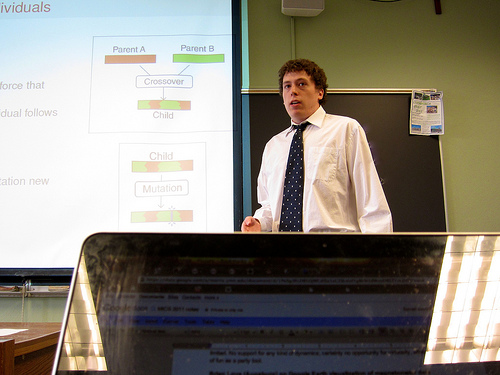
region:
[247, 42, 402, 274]
This is a person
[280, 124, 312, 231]
a black tie with wshite dots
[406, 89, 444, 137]
a news page attached to the wall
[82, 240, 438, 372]
the laptop displayed information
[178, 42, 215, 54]
the phrase parent B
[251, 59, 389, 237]
a man explaining about genetics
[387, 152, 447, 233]
an empty blackboard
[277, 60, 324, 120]
the head of the man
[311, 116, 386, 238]
the long sleeve white shirt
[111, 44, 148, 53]
the phrase Parent A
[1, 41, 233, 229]
the projection of the laptop display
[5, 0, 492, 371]
A man is giving a presentation.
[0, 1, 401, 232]
A man is standing next to a projecter screen.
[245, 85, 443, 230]
A blackboard is behind the man.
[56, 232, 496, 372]
A laptop is in the foreground.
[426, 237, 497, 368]
A light is reflected off the laptop screen.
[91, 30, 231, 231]
A graph is on the projector screen.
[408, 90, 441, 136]
A paper is hanging on the board.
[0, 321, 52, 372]
A wood table is partially visible.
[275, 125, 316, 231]
The man is wearing a tie.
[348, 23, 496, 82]
The wall is green.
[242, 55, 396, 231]
nervous guy presenting wearing blue tie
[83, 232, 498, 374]
Reflection on the computer screen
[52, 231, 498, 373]
Computer screen turned off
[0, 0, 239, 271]
Presentation projected on White background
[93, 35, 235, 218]
Flow chart on presentation.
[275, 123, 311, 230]
Blue and white polka dot tie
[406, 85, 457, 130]
Poster attached to the chalkboard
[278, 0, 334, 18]
White speaker box mounted to walk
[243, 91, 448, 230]
Black chalkboard behind kid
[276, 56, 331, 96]
Jewish Afro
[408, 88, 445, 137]
Paper with pictures on it and writing on the black board.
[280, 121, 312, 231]
Blue tie with white spots on it.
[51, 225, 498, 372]
Laptop that is switched on with the reflection of lights on it.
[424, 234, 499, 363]
Reflection of white lights on the laptop screen.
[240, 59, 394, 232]
A man in a long sleeve white shirt with curly brown hair.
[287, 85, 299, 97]
Nose on the face of a man.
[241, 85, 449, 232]
A black board behind a man.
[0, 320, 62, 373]
A brown wood desk.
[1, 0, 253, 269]
A white projector screen with a spreadsheet on it.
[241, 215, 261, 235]
Right hand of a curly brown haired man.